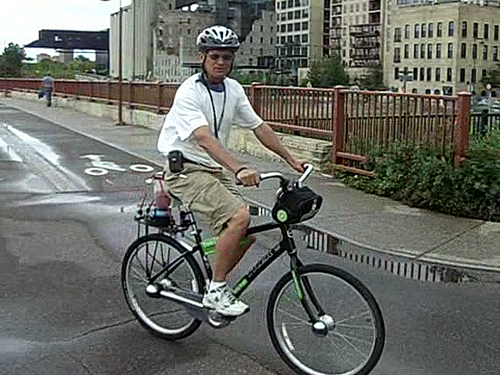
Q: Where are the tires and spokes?
A: On the two bike wheels.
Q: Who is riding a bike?
A: A man.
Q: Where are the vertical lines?
A: On the curb.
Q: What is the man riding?
A: Bicycle.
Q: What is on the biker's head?
A: Helmet.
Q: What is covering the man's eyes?
A: Sunglasses.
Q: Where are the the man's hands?
A: On the handlebars.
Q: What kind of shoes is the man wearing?
A: Sneakers.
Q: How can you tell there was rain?
A: Puddles.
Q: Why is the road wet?
A: It has rained.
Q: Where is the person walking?
A: On sidewalk.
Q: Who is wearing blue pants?
A: Person on bridge.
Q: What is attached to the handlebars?
A: A bag.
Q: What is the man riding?
A: Bike.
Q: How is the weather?
A: Cloudy.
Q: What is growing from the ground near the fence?
A: Bushes.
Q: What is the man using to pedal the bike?
A: Feet.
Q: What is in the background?
A: Buildings.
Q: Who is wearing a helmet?
A: Man on bike.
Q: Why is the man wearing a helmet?
A: Safety.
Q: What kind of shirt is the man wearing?
A: Short sleeved.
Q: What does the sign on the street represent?
A: Biker lane.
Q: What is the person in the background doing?
A: Walking.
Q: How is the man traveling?
A: By bike.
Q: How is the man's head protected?
A: With a helmet.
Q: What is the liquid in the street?
A: Rainwater.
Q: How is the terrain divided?
A: Sidewalk.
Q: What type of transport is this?
A: Bicycle.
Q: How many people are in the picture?
A: Two.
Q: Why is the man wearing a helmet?
A: To protect his head.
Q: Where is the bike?
A: On the road.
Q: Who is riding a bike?
A: A man.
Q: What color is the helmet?
A: Black and white.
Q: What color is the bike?
A: Black and green.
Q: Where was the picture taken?
A: Outside on the street.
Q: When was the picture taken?
A: During the day.